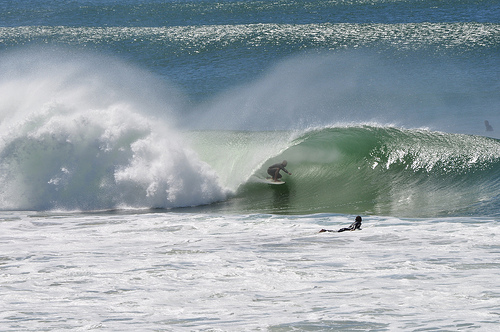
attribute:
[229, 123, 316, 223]
surfer — hanging ten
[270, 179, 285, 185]
surfboard — white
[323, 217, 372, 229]
person — paddling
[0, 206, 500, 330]
water — white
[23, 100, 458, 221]
wave — giant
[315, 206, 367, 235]
person — laying down 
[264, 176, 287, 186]
surfboard — white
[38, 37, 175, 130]
spray — white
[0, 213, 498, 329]
foam — white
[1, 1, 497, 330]
ocean — rough